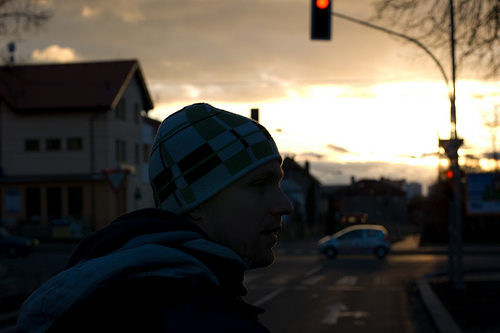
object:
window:
[74, 186, 90, 233]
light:
[308, 1, 334, 41]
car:
[313, 222, 390, 257]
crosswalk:
[239, 254, 413, 333]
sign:
[431, 140, 465, 150]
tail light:
[384, 238, 393, 249]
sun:
[412, 85, 491, 164]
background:
[131, 70, 499, 205]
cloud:
[16, 4, 499, 94]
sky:
[3, 6, 498, 183]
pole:
[325, 11, 450, 83]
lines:
[226, 265, 415, 295]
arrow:
[318, 293, 372, 328]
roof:
[5, 59, 157, 113]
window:
[48, 140, 67, 155]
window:
[66, 140, 81, 157]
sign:
[103, 162, 138, 202]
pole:
[117, 198, 123, 232]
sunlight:
[280, 74, 469, 146]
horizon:
[141, 94, 500, 195]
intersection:
[243, 225, 467, 333]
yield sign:
[96, 159, 141, 195]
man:
[14, 102, 286, 333]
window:
[20, 131, 42, 154]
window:
[23, 192, 44, 225]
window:
[135, 102, 142, 125]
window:
[132, 140, 141, 165]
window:
[109, 132, 127, 167]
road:
[241, 238, 499, 332]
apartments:
[2, 57, 259, 242]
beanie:
[145, 101, 284, 217]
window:
[111, 90, 135, 126]